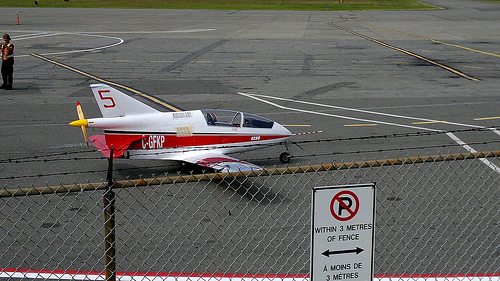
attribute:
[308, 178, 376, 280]
sign — no parking, white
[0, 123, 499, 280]
fence — chain link, rusty, metal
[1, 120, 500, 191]
wire — barbed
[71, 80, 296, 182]
plane — small, painted, white, red, aerodynamic, yellow, private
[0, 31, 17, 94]
person — standing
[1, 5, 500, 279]
runway — paved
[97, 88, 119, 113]
number — five, red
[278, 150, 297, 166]
wheel — landing gear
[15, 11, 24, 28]
cone — orange, bright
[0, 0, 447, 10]
grass — short, green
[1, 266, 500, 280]
stripes — painted, red, white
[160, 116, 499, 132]
stripe — dotted, yellow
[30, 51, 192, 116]
line — solid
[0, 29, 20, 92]
man — working